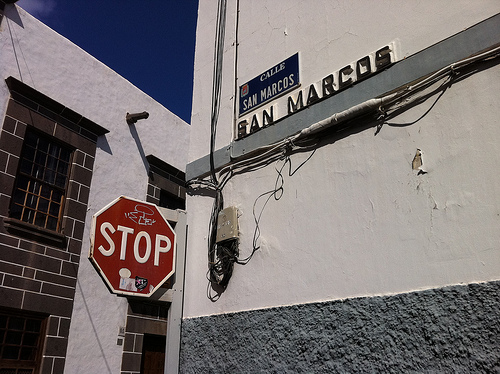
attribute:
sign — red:
[69, 181, 199, 319]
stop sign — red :
[87, 195, 176, 297]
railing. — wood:
[8, 117, 82, 246]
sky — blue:
[12, 0, 201, 126]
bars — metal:
[54, 192, 61, 236]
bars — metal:
[30, 182, 40, 224]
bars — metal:
[47, 187, 53, 227]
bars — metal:
[18, 180, 26, 226]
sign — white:
[81, 193, 188, 311]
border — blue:
[167, 7, 227, 171]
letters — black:
[230, 67, 414, 122]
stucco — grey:
[177, 289, 485, 368]